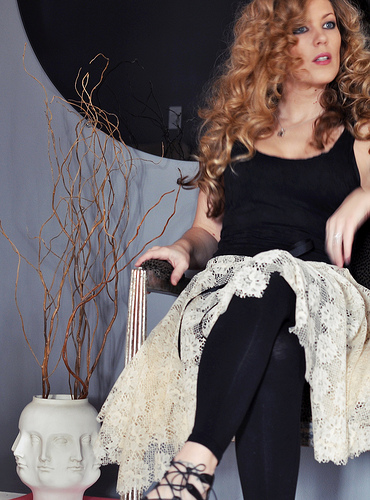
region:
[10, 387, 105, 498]
white container with faces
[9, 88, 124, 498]
curley sticks in a vase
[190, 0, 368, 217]
woman with curly hair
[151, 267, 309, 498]
legs crossed at the knees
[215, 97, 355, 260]
black shirt with scoop neck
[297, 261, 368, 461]
white lace material draped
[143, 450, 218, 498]
crisscrossed black laces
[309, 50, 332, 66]
pink lips and white teeth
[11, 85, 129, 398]
brown curly sticks without leaves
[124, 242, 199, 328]
hand on an armrest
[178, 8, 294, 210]
Very long curly hair.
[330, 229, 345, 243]
Woman wearing a ring.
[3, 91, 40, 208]
Blue wall in the background.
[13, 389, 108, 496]
White planter on the floor.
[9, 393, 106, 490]
White planter with faces.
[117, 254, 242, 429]
Lacy shaw worn on the knees.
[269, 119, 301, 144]
Woman wearing a necklace.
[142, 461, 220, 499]
Shoes that tie at the ankle.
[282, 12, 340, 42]
Woman is wearing eye make up.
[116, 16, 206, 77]
Large round mirror on the wall.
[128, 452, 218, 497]
Woman is wearing shoes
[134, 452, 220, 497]
Woman is wearing black shoes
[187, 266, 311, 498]
Woman is wearing tights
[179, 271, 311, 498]
Woman is wearing black tights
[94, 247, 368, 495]
Woman is wearing a skirt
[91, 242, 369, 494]
Woman is wearing a white skirt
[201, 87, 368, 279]
Woman is wearing a shirt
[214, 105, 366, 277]
Woman is wearing a black shirt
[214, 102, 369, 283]
Woman is wearing a tank top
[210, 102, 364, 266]
Woman is wearing a black tank top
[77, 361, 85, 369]
part of a branch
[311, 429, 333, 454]
part of a curtain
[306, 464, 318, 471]
part of a wall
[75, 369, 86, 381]
part of a branch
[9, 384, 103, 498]
white vase beside chair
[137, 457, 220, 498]
black lace up shoes of woman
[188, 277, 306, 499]
black leggings woman is wearing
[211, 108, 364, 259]
black tank top woman is wearing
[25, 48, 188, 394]
dried branches in the vase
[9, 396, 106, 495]
faces sculpted into white vase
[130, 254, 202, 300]
armrest of chair woman is sitting in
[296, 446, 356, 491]
shadow on wall beneath chair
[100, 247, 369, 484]
lace material across woman's lap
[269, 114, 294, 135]
necklace woman is wearing